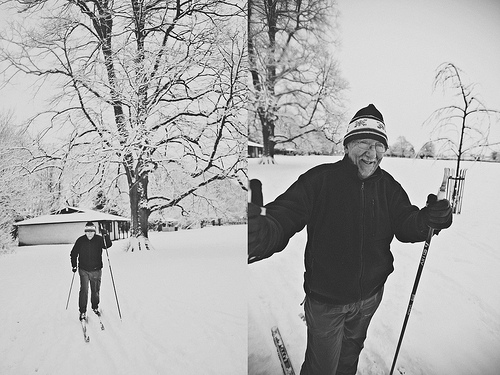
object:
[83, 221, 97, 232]
balaclava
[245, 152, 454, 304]
fleece jacket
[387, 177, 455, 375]
pole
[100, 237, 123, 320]
skis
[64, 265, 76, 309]
skis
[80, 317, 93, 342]
snowboard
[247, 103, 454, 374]
he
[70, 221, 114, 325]
he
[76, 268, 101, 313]
black pants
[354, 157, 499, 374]
ground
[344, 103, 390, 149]
cap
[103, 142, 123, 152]
snow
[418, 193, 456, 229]
hand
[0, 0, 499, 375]
winter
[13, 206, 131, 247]
building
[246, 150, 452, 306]
black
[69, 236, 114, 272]
black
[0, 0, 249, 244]
barren tree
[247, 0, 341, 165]
barren tree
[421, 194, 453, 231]
glove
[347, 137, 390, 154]
eye glasses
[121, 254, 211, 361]
snow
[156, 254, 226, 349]
manhole cover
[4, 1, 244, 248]
tree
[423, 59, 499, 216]
tree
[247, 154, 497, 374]
snow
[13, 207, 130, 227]
roof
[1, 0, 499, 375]
landscape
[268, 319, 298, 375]
ski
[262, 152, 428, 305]
sweater